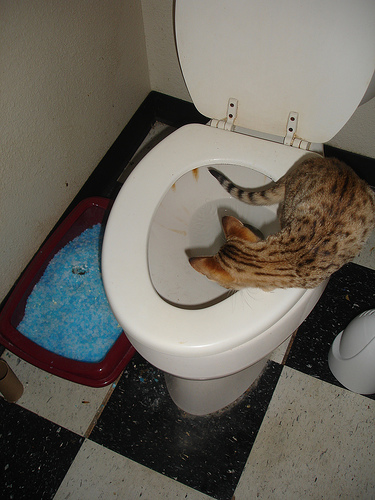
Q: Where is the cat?
A: On the toilet seat.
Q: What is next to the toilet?
A: The litter box.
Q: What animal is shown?
A: Cat.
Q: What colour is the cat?
A: Orange and black.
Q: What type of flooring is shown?
A: Tile.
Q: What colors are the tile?
A: Black and white.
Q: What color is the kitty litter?
A: Blue.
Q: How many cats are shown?
A: One.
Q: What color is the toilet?
A: White.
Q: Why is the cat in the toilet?
A: The seat is up.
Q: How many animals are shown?
A: One.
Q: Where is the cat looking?
A: In the toilet.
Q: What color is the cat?
A: Brown.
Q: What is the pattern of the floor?
A: Checkers.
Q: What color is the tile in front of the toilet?
A: Black.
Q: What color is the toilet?
A: White.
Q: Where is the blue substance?
A: Litter box.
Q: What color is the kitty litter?
A: Blue.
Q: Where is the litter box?
A: Left side of toilet.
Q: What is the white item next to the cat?
A: Toilet bowl brush.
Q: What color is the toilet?
A: White.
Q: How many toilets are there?
A: One.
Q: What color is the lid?
A: White.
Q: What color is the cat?
A: Brown.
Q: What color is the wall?
A: White.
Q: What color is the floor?
A: Black and white.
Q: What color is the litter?
A: Blue.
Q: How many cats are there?
A: One.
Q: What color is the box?
A: Red.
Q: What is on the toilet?
A: A cat.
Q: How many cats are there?
A: One.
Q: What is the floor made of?
A: Tile.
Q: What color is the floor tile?
A: Black and white.